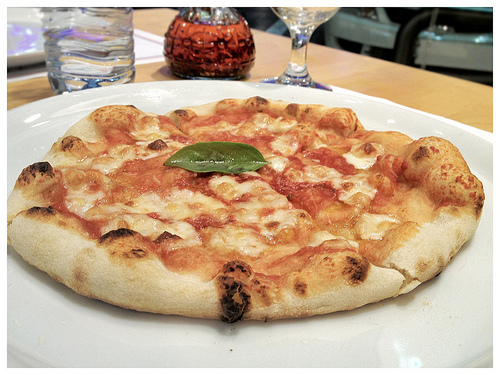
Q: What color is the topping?
A: Green.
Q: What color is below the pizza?
A: White.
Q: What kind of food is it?
A: Pizza.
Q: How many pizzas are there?
A: One.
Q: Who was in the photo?
A: No one.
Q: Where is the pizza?
A: On the table.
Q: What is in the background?
A: A table.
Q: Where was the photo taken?
A: In a restaurant.